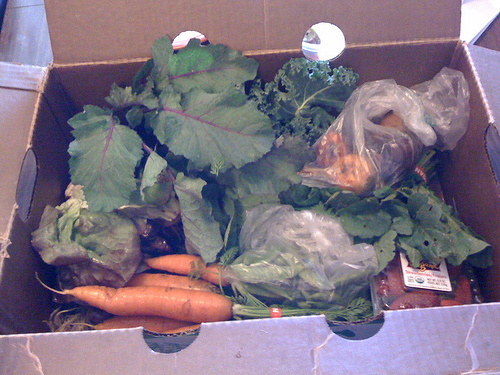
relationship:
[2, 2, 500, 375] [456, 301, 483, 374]
cardboard has crack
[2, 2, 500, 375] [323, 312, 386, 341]
cardboard has cutout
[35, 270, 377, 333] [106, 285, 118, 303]
carrot has spot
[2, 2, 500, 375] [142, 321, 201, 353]
cardboard has cutout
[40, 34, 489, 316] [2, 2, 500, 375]
food in cardboard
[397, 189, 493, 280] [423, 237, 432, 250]
leaf has hole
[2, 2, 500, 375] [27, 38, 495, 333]
cardboard contains food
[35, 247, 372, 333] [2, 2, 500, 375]
carrots in cardboard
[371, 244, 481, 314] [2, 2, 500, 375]
strawberries in cardboard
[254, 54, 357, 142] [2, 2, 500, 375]
lettuce in cardboard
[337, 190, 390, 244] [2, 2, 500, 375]
kale in cardboard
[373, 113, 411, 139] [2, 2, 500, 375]
radish in cardboard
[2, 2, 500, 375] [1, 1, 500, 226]
cardboard on table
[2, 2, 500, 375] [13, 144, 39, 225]
cardboard has handle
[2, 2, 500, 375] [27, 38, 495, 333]
cardboard filled with food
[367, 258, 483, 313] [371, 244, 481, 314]
container contains strawberries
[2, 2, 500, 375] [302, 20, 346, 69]
cardboard has hole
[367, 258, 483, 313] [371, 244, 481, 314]
container has strawberries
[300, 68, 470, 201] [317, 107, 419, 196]
bag contains vegetables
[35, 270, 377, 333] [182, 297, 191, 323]
carrot has dirt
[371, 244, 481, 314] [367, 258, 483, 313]
strawberries in container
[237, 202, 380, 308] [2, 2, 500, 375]
bag in cardboard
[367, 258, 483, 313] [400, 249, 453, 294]
container has label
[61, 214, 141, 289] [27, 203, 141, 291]
peas in bag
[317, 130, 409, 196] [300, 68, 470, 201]
peppers in bag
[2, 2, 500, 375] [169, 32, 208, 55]
cardboard has hole